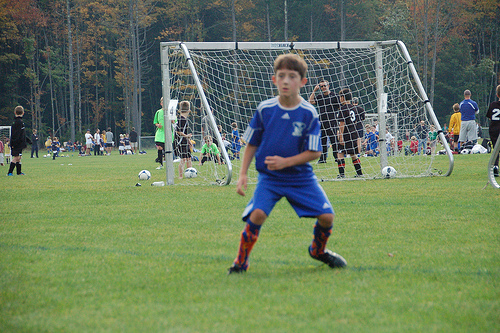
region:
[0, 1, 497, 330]
A soccer tournament at practice time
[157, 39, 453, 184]
The goal set up to go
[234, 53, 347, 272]
A young boy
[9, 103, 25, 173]
A young soccer player with black socks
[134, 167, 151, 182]
A soccer ball sits in the grass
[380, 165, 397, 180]
a goal was made at some point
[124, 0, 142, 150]
Tall trees are in the background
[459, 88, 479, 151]
A coach watches his players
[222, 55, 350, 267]
A young boy is ready to react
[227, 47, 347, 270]
Wearing a blue soccer jersey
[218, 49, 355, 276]
The boy in blue nearest the camera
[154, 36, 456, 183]
The net behind the boy in blue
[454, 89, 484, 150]
The man in the blue shirt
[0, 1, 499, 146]
The trees in the background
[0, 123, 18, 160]
The goal at the far end of the field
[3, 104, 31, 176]
The person in all black on the left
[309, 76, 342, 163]
The man in black behind the net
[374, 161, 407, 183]
The soccer ball in the net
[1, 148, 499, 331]
The grass field the kids are playing on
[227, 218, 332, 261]
The shin guards of the nearest boy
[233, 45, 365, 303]
boy playing soccer game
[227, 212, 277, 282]
Boy has orange shin guard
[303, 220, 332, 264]
Boy has orange shin guard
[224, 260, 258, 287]
Boy wearing black soccer shoe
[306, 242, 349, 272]
Boy wearing black soccer shoe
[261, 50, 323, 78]
Boy has dark brown hair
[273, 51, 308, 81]
Boys hair is thick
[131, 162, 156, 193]
Soccer ball laying on grass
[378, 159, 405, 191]
Soccer ball laying against net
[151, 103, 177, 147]
Boy wearing bright green shirt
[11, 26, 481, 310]
children playing soccer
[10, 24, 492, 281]
boys on a soccer field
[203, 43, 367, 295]
a boy in a blue and white Adidas outfit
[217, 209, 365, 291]
blue and orange soccer socks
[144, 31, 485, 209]
a soccer goal net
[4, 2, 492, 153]
the woods in the distance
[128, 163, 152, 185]
a soccer ball sitting in the grass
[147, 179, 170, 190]
a water bottle laying next to the goal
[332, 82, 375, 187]
a boy in a black uniform with the number 3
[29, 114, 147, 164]
parents and families hanging out in the distance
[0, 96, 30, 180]
a person is standing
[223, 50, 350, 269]
a person is standing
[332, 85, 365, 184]
a person is standing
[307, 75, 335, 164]
a person is standing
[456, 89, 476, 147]
a person is standing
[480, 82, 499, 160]
a person is standing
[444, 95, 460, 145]
a person is standing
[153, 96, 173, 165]
a person is standing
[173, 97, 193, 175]
a person is standing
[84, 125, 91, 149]
a person is standing